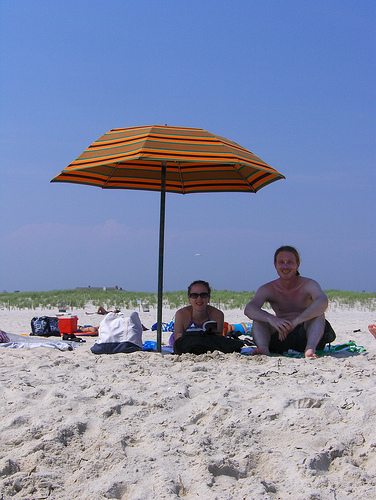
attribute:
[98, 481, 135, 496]
imprints — small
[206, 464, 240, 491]
imprint — small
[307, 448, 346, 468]
imprint — small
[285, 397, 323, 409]
imprint — small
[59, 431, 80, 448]
imprint — small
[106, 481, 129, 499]
imprint — small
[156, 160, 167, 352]
pole — brown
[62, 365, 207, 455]
imprints — small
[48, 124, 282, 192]
umbrella — large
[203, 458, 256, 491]
imprints — small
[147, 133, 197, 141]
stripes — yellow, black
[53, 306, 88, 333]
cooler — red and white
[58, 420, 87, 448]
imprint — small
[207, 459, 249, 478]
imprint — small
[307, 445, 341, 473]
imprint — small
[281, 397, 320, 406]
imprint — small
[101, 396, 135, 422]
imprint — small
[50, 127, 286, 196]
umbrella — multi colored, striped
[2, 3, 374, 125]
sky — clear, blue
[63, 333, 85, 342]
sandal — black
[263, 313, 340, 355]
shorts — black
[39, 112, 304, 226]
umbrella — orange, black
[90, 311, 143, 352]
bag — white, blue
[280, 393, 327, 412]
imprint — small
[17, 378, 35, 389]
imprint — small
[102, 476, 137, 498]
imprint — small